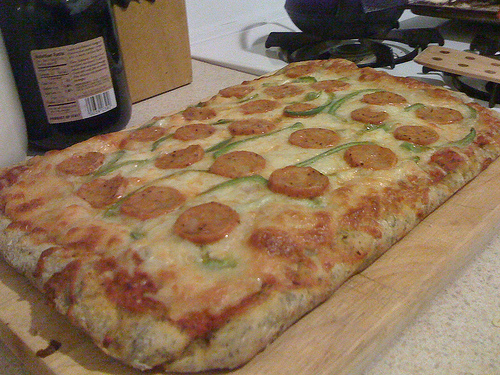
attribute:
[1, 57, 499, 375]
pizza — tasty, delicious, ready, flavorful, large, delightful, full size, full sized, cooked, rectangular, brown, tan, big, cheesy, deep dish, homemade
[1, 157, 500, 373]
board — wooden, wood, tan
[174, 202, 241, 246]
pepperoni — delicious, piece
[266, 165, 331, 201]
pepperoni — delicious, piece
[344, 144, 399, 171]
pepperoni — delicious, piece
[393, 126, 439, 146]
pepperoni — delicious, piece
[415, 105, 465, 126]
pepperoni — delicious, piece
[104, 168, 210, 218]
green pepper — slice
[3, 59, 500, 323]
cheese — cooked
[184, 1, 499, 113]
oven — white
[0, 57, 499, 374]
counter top — beige, beautiful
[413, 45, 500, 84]
spatula — wooden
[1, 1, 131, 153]
bottle — brown, wine, dark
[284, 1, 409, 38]
pan — black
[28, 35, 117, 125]
label — tan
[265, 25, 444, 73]
burner — gas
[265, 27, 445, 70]
grate — metal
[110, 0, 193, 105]
block — wooden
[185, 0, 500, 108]
range — gas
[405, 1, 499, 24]
tray — metal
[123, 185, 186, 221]
meat — round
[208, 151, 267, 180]
meat — round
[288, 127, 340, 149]
meat — round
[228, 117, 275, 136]
meat — round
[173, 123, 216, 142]
meat — round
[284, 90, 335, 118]
pepper — sliced, green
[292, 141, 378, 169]
pepper — sliced, green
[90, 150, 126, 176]
pepper — sliced, green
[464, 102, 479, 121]
pepper — sliced, green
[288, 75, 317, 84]
pepper — sliced, green